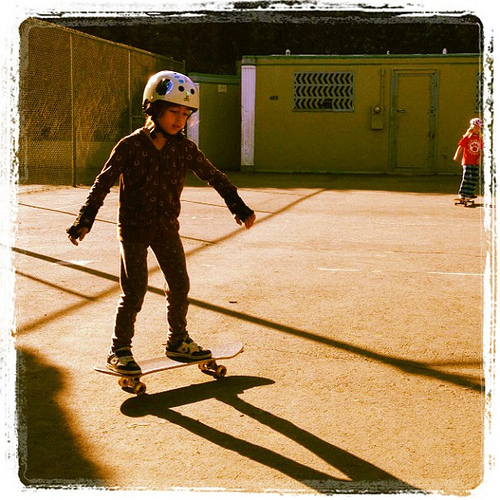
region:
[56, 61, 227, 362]
young girl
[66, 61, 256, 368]
young skateboard rider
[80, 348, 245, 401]
a child sized skateboard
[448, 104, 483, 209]
blond child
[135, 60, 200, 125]
child sized protective helmet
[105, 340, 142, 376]
shoe that is meant for skateboarding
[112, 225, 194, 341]
loose fitting child sized sweat pants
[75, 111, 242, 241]
stylish childrens sweater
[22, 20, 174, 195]
old looking chain link fence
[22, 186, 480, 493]
clear asphalt ground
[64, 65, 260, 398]
a kid on a skateboard.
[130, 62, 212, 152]
a kid wearing helmet.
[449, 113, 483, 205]
a little girl on a skateboard.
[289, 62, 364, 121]
a window on the side of a building.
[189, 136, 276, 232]
a left arm of a person.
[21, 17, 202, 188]
a fence on a parking lot.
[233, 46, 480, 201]
a house on a parking lot.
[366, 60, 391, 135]
a gas meter on a house.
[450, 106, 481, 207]
a person in a red outfit.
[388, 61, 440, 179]
An entrance.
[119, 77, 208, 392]
kid riding brown skateboard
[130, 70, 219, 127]
kid wearing pink helmet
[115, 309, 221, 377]
kid wearing black and white shoes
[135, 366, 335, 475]
shadow of kid on skateboard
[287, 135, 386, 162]
building in background is olive green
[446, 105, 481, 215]
girl in red shirt riding skateboard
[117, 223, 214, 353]
kid wearing brown pants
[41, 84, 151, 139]
tall chain link fence in background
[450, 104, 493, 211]
girl in blue skirt riding skateboard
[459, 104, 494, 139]
girl wearing safety helmet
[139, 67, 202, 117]
White helmet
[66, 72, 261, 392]
Child on a skateboard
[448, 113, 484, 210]
Girl with blond hair on a skateboard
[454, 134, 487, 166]
Red t-shirt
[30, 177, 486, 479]
Concrete playground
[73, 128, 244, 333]
Brown outfit with white designs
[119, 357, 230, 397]
Four small wheels on the bottom of a skateboard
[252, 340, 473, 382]
A crack in the pavement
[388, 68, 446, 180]
A yellow door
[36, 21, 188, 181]
A tall metal fence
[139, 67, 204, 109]
The white helmet on the kid's head.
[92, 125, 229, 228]
The brown sweater the kid is wearing.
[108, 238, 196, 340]
The brown pants the kid is wearing.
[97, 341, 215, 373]
The kid's black and white sneakers.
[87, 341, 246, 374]
The skateboard the kid in the brown sweater is riding.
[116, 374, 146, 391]
The back wheels of the skateboard the kid is riding in the brown sweater.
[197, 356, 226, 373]
The front wheels the kid is riding in the brown sweater.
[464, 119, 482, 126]
The pink helmet the girl on the right is wearing.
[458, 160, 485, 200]
The plaid skirt the girl on the right is wearing.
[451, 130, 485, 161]
The red t-shirt the girl on the right is wearing.